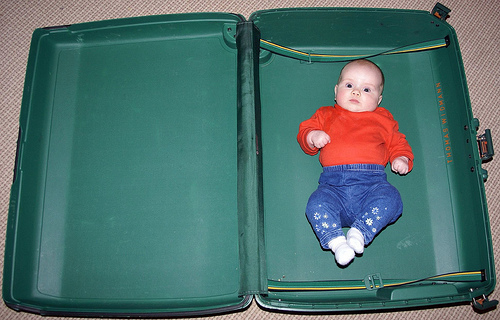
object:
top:
[297, 108, 423, 165]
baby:
[297, 57, 415, 265]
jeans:
[303, 163, 403, 250]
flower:
[365, 218, 373, 224]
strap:
[257, 31, 449, 63]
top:
[0, 12, 257, 317]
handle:
[479, 129, 496, 157]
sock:
[329, 236, 354, 266]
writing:
[435, 78, 456, 166]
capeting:
[1, 2, 499, 318]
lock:
[471, 128, 495, 164]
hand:
[310, 129, 329, 149]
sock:
[347, 228, 367, 254]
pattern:
[312, 207, 381, 238]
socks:
[326, 228, 365, 266]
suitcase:
[0, 6, 496, 320]